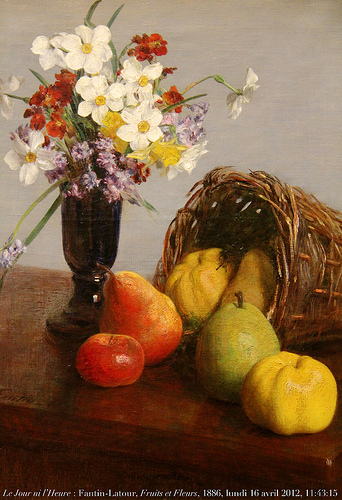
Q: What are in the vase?
A: Flowers.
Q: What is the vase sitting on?
A: A table.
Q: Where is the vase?
A: On a table.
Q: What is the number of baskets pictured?
A: One.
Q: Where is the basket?
A: On a table.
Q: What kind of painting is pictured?
A: A still life.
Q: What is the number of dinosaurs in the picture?
A: Zero.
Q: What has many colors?
A: Flowers.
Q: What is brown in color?
A: The table.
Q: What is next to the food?
A: A basket.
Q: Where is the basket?
A: Next to the food.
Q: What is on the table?
A: Vase.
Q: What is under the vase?
A: Fruit.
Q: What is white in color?
A: Some flowers.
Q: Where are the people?
A: None in photo.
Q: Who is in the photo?
A: No people.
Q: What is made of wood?
A: The table.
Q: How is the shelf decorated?
A: Flowers and fruit basket.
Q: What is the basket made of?
A: Wicker.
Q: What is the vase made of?
A: Glass.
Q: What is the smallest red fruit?
A: Apple.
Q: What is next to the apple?
A: Pear.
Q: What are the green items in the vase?
A: Filler leaves.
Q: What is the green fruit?
A: Pear.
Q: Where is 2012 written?
A: On the bottom.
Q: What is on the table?
A: Fruits.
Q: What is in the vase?
A: Flowers.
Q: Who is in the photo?
A: Nobody.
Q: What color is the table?
A: Brown.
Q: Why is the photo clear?
A: Its during the day.